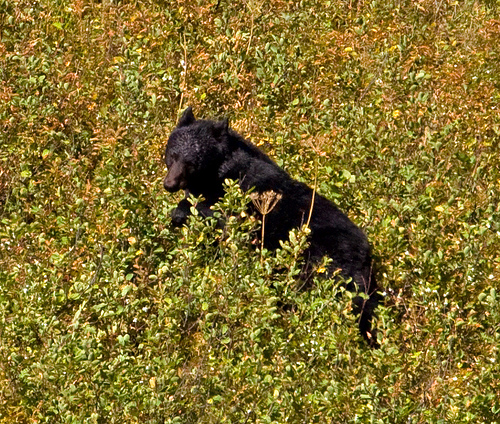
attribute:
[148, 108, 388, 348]
bear — black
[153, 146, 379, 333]
bear — black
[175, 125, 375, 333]
bear — black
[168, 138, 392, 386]
bear — black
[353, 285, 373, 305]
fur — black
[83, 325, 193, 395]
leaves — green and brown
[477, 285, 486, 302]
leaf — green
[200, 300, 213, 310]
leaf — green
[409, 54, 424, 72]
leaf — green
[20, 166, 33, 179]
leaf — green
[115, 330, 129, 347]
leaf — green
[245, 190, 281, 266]
twig — yellow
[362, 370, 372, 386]
leaf — green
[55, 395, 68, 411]
leaf — green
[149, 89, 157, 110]
leaf — green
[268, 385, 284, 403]
leaf — green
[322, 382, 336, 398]
leaf — green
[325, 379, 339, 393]
leaf — green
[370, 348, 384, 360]
leaf — green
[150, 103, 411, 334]
dog — black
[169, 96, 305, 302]
dog — black